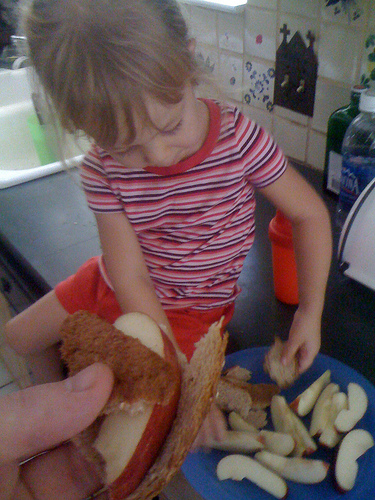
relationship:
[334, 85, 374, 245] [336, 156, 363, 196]
bottle with label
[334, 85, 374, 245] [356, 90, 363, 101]
bottle with lid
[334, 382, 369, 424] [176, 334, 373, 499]
apple slice on plate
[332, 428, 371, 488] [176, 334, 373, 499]
apple slice on plate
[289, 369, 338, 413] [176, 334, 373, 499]
apple slice on plate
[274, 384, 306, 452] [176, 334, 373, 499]
apple slice on plate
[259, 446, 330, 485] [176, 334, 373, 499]
apple slice on plate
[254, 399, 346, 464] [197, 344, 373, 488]
apple on plate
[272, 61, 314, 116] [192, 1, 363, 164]
swich on wall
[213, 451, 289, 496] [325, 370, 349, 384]
slice on plate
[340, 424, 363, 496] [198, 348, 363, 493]
slice on plate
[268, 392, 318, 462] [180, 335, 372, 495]
apple in dish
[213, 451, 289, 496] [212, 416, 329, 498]
slice of apple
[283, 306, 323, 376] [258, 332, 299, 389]
hand holding bread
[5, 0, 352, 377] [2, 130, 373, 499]
girl sitting on counter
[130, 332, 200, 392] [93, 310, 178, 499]
hand holding apple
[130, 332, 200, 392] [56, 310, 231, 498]
hand holding bread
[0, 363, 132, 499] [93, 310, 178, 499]
hand holding apple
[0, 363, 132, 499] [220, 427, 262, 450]
hand holding apple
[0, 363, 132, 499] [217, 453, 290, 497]
hand holding apple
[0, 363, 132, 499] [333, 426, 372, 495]
hand holding apple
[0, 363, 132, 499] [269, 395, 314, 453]
hand holding apple